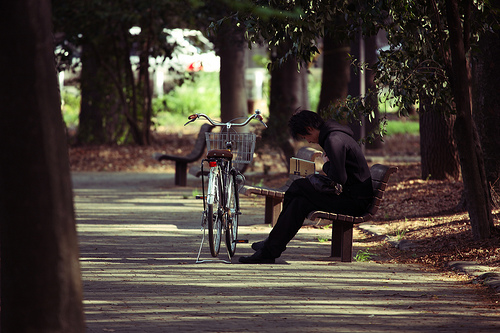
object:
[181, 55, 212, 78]
people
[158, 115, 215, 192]
bench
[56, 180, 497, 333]
bike path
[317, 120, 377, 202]
sweatshirt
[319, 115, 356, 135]
hood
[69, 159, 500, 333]
walkway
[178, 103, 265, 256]
bike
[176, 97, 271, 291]
ground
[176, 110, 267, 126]
handle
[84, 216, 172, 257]
sunlight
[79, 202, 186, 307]
ground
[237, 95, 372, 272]
person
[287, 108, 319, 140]
head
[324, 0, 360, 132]
trunk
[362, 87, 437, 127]
grass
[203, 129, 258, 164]
basket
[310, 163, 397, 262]
chair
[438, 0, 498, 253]
tree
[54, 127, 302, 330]
path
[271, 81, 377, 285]
man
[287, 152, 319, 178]
book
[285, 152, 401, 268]
bench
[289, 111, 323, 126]
short hair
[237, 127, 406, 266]
bench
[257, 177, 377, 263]
pants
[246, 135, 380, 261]
clothes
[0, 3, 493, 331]
park